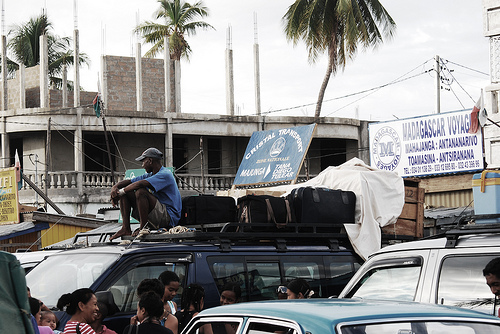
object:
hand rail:
[14, 168, 315, 194]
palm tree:
[281, 0, 393, 120]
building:
[0, 19, 369, 189]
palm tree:
[135, 0, 211, 115]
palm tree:
[1, 10, 86, 103]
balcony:
[3, 167, 324, 195]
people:
[131, 293, 175, 333]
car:
[179, 299, 495, 333]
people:
[60, 286, 98, 333]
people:
[174, 283, 213, 332]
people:
[159, 270, 179, 313]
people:
[283, 278, 317, 300]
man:
[110, 148, 182, 243]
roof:
[64, 238, 353, 250]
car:
[12, 230, 367, 334]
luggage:
[240, 188, 357, 230]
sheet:
[220, 157, 405, 266]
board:
[367, 109, 482, 179]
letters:
[397, 116, 480, 174]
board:
[230, 124, 318, 187]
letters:
[237, 130, 303, 179]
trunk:
[471, 170, 500, 222]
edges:
[472, 169, 500, 179]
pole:
[254, 47, 262, 114]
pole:
[227, 49, 234, 119]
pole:
[164, 33, 171, 112]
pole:
[136, 43, 143, 111]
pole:
[73, 29, 81, 110]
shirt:
[132, 163, 183, 226]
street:
[5, 236, 414, 332]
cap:
[135, 148, 163, 161]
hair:
[57, 288, 96, 317]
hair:
[140, 291, 163, 317]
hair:
[286, 278, 313, 299]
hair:
[183, 282, 204, 323]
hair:
[158, 271, 179, 286]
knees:
[136, 188, 151, 202]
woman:
[30, 297, 51, 332]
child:
[40, 311, 59, 333]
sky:
[1, 1, 488, 121]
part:
[389, 18, 463, 76]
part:
[79, 104, 109, 140]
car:
[340, 233, 500, 312]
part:
[409, 246, 442, 312]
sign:
[0, 165, 17, 226]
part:
[165, 182, 174, 203]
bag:
[237, 195, 290, 226]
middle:
[234, 195, 301, 231]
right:
[357, 75, 495, 208]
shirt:
[65, 319, 95, 333]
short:
[144, 196, 170, 230]